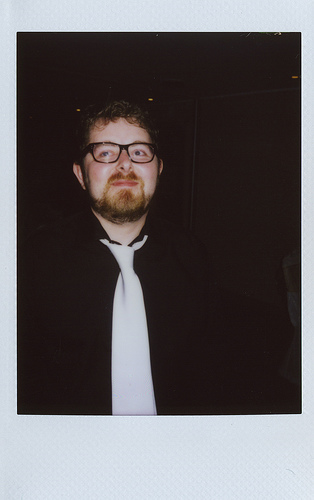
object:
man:
[37, 98, 226, 418]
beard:
[90, 169, 150, 224]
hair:
[78, 97, 162, 160]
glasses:
[80, 141, 161, 163]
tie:
[100, 235, 158, 416]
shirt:
[34, 206, 241, 416]